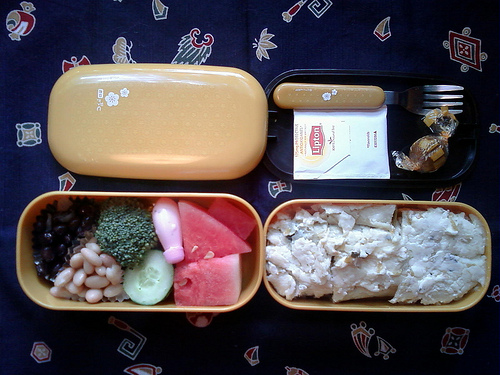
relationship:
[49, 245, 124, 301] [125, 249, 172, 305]
beans next to cucumber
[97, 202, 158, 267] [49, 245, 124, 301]
broccoli next to beans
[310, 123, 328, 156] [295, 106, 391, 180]
label on envelope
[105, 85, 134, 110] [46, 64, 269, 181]
flowers on cover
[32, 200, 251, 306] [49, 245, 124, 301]
meal with beans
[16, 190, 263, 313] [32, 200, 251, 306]
container with food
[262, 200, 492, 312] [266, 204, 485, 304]
container with food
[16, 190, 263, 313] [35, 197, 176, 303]
container with vegetables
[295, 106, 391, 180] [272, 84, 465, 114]
envelope with fork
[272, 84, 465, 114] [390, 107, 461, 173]
fork with candy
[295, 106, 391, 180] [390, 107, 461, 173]
envelope with candy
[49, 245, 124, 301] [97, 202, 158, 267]
beans and broccoli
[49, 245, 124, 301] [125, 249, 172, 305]
beans and cucumber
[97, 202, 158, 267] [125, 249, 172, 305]
broccoli and cucumber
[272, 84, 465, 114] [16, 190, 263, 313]
fork matchers container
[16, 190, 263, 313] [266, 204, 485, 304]
container filled with food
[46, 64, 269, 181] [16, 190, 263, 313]
cover of container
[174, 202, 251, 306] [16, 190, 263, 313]
watermelon in container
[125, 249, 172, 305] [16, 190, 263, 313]
cucumber in container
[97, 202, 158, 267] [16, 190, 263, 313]
broccoli in container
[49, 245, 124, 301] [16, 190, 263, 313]
beans in container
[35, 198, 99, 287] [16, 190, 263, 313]
black beans in container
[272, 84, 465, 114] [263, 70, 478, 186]
fork on plastic container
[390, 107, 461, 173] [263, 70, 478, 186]
candy on plastic container